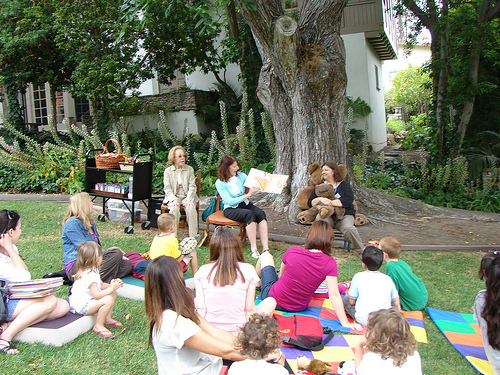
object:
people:
[254, 219, 368, 332]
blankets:
[421, 304, 500, 374]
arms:
[330, 184, 355, 207]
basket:
[95, 139, 129, 171]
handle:
[98, 138, 124, 154]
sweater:
[214, 171, 250, 211]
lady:
[311, 159, 367, 251]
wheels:
[122, 224, 137, 236]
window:
[31, 82, 48, 126]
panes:
[29, 79, 54, 128]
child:
[228, 314, 292, 374]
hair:
[234, 313, 283, 359]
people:
[142, 253, 283, 373]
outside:
[0, 0, 500, 374]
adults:
[192, 225, 280, 336]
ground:
[0, 193, 500, 373]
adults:
[43, 189, 131, 286]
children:
[340, 306, 422, 373]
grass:
[0, 200, 488, 373]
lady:
[214, 152, 272, 257]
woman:
[160, 145, 202, 244]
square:
[431, 320, 475, 333]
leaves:
[8, 3, 105, 70]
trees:
[0, 0, 275, 170]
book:
[244, 166, 289, 196]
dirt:
[0, 191, 500, 246]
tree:
[201, 0, 500, 232]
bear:
[295, 161, 369, 227]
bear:
[305, 181, 344, 222]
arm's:
[305, 189, 330, 209]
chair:
[162, 166, 202, 230]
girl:
[255, 220, 366, 334]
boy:
[343, 242, 401, 327]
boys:
[377, 233, 429, 313]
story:
[242, 166, 289, 194]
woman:
[0, 206, 73, 356]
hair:
[0, 208, 19, 239]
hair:
[155, 210, 177, 234]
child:
[69, 240, 124, 338]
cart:
[82, 148, 154, 234]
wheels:
[96, 212, 109, 223]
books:
[4, 275, 62, 299]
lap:
[34, 292, 62, 312]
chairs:
[204, 192, 248, 246]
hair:
[305, 219, 336, 257]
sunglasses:
[6, 210, 21, 223]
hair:
[143, 254, 199, 351]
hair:
[360, 306, 419, 366]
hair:
[74, 239, 104, 277]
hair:
[362, 243, 384, 272]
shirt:
[383, 258, 429, 311]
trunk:
[255, 17, 352, 184]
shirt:
[60, 215, 100, 267]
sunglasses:
[177, 152, 188, 159]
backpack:
[270, 313, 335, 352]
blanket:
[254, 283, 427, 374]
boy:
[145, 211, 199, 276]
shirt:
[145, 232, 181, 261]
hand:
[246, 185, 262, 195]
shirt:
[268, 246, 337, 312]